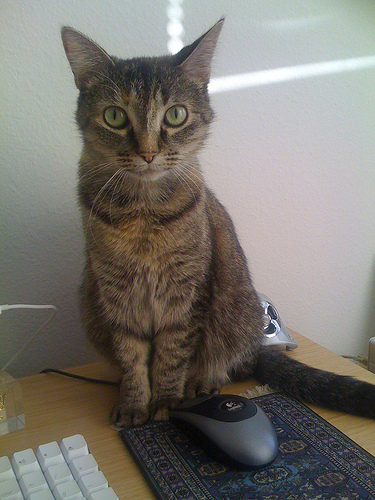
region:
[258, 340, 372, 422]
cat's tail is dark gray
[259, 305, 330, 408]
cat's tail is dark gray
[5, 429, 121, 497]
the keyboard is white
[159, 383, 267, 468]
a mouse on mousepad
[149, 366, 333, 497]
a mouse on mousepad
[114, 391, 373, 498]
a colorful mousepad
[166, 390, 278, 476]
a gray and black mouse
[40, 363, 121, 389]
the black cord of a mouse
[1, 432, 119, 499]
a white keyboard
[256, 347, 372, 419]
th dark gray tail of a mouse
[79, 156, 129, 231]
white cat whiskers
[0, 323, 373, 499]
a light brown desk top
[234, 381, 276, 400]
a fringe on a mouse pad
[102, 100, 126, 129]
a green cat eye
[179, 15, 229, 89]
an alert cat ear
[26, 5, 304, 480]
The cat sitting on the table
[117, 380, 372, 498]
The mouse pad on the desk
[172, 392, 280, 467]
The mouse on the desk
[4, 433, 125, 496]
The keyboard of the desk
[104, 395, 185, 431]
The paws on the cat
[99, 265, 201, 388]
The legs of the cat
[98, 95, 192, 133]
The eyes of the cat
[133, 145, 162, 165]
The nose of the cat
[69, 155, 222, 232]
The whiskers on the cat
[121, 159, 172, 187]
The mouth of the cat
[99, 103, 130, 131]
one right green cat eye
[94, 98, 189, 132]
two round green cat eyes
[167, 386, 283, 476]
one silver and black computer mouse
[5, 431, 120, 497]
edge of white computer keyboard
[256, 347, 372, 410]
one black cat tail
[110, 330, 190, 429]
two brown and black cat legs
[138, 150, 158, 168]
one pink cat nose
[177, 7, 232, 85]
one left pointed cat ear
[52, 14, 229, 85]
two light brown cat ears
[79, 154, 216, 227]
long white cat whiskers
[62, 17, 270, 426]
Gray and brown cat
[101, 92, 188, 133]
Yellowish eyes of a cat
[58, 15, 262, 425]
Cat sitting on a desk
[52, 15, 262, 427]
Cat looking at the camera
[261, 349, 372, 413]
Black tail of a cat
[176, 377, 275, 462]
Gray and black mouse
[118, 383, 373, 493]
Blue mat on desk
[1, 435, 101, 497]
White keys of a keyboard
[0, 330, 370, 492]
Brown desk made of wood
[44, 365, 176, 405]
Thin black mouse cable